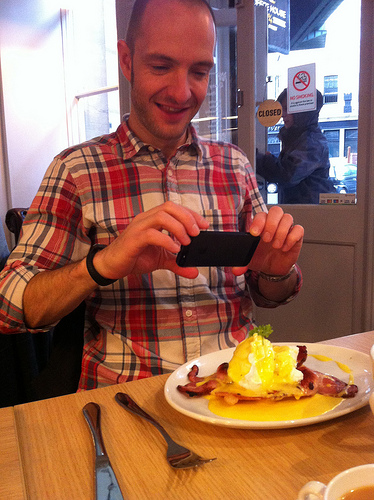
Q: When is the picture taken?
A: During the daytime.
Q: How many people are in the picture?
A: Two people.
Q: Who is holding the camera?
A: The man.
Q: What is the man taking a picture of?
A: Food.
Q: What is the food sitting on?
A: The plate.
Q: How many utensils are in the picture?
A: Two utensils.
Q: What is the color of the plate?
A: White.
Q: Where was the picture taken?
A: A restaurant.